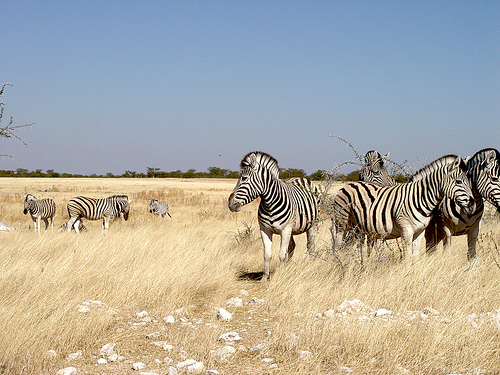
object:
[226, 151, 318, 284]
zebra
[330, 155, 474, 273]
zebra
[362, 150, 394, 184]
zebra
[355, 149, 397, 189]
middle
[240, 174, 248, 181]
eye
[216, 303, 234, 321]
stone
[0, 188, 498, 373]
grass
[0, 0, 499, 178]
sky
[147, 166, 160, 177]
tree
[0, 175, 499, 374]
field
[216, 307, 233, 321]
rock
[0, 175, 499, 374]
ground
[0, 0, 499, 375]
background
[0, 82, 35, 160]
branches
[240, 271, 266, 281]
shadow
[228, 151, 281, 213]
head